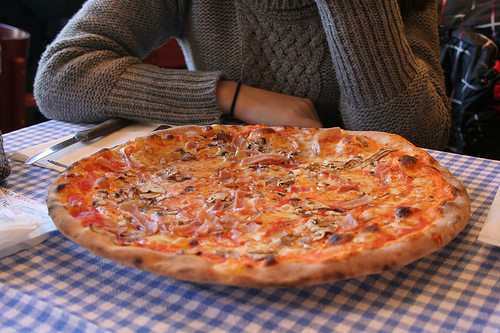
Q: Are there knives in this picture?
A: Yes, there is a knife.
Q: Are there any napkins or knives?
A: Yes, there is a knife.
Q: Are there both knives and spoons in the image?
A: No, there is a knife but no spoons.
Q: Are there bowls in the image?
A: No, there are no bowls.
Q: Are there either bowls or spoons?
A: No, there are no bowls or spoons.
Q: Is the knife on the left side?
A: Yes, the knife is on the left of the image.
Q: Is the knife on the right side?
A: No, the knife is on the left of the image.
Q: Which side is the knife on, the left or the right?
A: The knife is on the left of the image.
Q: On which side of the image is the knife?
A: The knife is on the left of the image.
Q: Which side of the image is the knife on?
A: The knife is on the left of the image.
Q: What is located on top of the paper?
A: The knife is on top of the paper.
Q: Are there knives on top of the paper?
A: Yes, there is a knife on top of the paper.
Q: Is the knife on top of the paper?
A: Yes, the knife is on top of the paper.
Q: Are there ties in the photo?
A: Yes, there is a tie.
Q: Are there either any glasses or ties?
A: Yes, there is a tie.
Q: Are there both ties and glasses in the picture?
A: No, there is a tie but no glasses.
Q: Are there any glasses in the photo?
A: No, there are no glasses.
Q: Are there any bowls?
A: No, there are no bowls.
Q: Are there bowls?
A: No, there are no bowls.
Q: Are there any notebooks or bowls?
A: No, there are no bowls or notebooks.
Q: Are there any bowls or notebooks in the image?
A: No, there are no bowls or notebooks.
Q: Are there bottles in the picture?
A: No, there are no bottles.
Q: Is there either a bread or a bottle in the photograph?
A: No, there are no bottles or breads.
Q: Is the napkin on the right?
A: Yes, the napkin is on the right of the image.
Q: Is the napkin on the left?
A: No, the napkin is on the right of the image.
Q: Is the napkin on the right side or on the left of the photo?
A: The napkin is on the right of the image.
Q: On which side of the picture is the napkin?
A: The napkin is on the right of the image.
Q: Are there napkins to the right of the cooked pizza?
A: Yes, there is a napkin to the right of the pizza.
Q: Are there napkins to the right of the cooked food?
A: Yes, there is a napkin to the right of the pizza.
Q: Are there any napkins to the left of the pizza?
A: No, the napkin is to the right of the pizza.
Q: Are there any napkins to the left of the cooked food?
A: No, the napkin is to the right of the pizza.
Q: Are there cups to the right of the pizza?
A: No, there is a napkin to the right of the pizza.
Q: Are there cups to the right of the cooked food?
A: No, there is a napkin to the right of the pizza.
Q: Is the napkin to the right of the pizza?
A: Yes, the napkin is to the right of the pizza.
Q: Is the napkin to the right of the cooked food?
A: Yes, the napkin is to the right of the pizza.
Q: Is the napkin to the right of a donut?
A: No, the napkin is to the right of the pizza.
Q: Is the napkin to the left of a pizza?
A: No, the napkin is to the right of a pizza.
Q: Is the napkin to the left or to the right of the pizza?
A: The napkin is to the right of the pizza.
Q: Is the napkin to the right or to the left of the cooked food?
A: The napkin is to the right of the pizza.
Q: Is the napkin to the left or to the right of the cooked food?
A: The napkin is to the right of the pizza.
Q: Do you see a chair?
A: Yes, there is a chair.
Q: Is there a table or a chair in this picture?
A: Yes, there is a chair.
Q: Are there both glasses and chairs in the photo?
A: No, there is a chair but no glasses.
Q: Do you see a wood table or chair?
A: Yes, there is a wood chair.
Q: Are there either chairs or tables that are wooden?
A: Yes, the chair is wooden.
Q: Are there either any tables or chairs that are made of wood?
A: Yes, the chair is made of wood.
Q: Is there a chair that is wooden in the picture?
A: Yes, there is a wood chair.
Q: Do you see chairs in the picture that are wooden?
A: Yes, there is a chair that is wooden.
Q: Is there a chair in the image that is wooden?
A: Yes, there is a chair that is wooden.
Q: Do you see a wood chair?
A: Yes, there is a chair that is made of wood.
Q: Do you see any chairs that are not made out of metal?
A: Yes, there is a chair that is made of wood.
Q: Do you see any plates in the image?
A: No, there are no plates.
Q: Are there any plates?
A: No, there are no plates.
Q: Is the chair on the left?
A: Yes, the chair is on the left of the image.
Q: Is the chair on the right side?
A: No, the chair is on the left of the image.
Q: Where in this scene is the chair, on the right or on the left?
A: The chair is on the left of the image.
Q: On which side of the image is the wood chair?
A: The chair is on the left of the image.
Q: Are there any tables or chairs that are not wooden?
A: No, there is a chair but it is wooden.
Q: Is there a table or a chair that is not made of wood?
A: No, there is a chair but it is made of wood.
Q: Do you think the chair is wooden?
A: Yes, the chair is wooden.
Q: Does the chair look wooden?
A: Yes, the chair is wooden.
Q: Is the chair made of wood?
A: Yes, the chair is made of wood.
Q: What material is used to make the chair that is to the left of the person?
A: The chair is made of wood.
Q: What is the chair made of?
A: The chair is made of wood.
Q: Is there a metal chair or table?
A: No, there is a chair but it is wooden.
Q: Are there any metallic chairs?
A: No, there is a chair but it is wooden.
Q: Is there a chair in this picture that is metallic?
A: No, there is a chair but it is wooden.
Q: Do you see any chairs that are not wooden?
A: No, there is a chair but it is wooden.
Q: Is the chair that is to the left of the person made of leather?
A: No, the chair is made of wood.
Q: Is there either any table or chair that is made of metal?
A: No, there is a chair but it is made of wood.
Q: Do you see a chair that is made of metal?
A: No, there is a chair but it is made of wood.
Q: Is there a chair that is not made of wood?
A: No, there is a chair but it is made of wood.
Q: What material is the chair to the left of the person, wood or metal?
A: The chair is made of wood.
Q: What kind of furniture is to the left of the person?
A: The piece of furniture is a chair.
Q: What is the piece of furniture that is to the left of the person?
A: The piece of furniture is a chair.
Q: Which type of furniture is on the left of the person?
A: The piece of furniture is a chair.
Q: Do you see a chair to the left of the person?
A: Yes, there is a chair to the left of the person.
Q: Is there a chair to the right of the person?
A: No, the chair is to the left of the person.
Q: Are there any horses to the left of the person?
A: No, there is a chair to the left of the person.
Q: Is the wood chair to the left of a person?
A: Yes, the chair is to the left of a person.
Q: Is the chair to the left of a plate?
A: No, the chair is to the left of a person.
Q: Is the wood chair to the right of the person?
A: No, the chair is to the left of the person.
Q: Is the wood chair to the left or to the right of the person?
A: The chair is to the left of the person.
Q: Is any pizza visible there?
A: Yes, there is a pizza.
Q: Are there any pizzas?
A: Yes, there is a pizza.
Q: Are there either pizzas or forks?
A: Yes, there is a pizza.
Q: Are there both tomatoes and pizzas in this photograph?
A: No, there is a pizza but no tomatoes.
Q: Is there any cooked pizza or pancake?
A: Yes, there is a cooked pizza.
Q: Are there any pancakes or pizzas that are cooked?
A: Yes, the pizza is cooked.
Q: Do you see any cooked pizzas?
A: Yes, there is a cooked pizza.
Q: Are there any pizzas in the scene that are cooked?
A: Yes, there is a pizza that is cooked.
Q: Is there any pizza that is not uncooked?
A: Yes, there is an cooked pizza.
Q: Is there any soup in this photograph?
A: No, there is no soup.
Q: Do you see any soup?
A: No, there is no soup.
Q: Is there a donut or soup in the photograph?
A: No, there are no soup or donuts.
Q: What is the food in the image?
A: The food is a pizza.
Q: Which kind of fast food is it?
A: The food is a pizza.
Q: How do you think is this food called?
A: This is a pizza.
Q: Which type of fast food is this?
A: This is a pizza.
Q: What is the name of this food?
A: This is a pizza.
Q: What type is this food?
A: This is a pizza.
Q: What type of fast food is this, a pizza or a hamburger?
A: This is a pizza.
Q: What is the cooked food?
A: The food is a pizza.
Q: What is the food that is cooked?
A: The food is a pizza.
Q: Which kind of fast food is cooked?
A: The fast food is a pizza.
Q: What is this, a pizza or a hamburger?
A: This is a pizza.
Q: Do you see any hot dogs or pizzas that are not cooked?
A: No, there is a pizza but it is cooked.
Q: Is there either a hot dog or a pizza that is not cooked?
A: No, there is a pizza but it is cooked.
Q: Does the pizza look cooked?
A: Yes, the pizza is cooked.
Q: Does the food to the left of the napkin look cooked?
A: Yes, the pizza is cooked.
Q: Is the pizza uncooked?
A: No, the pizza is cooked.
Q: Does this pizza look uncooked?
A: No, the pizza is cooked.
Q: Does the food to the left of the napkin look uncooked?
A: No, the pizza is cooked.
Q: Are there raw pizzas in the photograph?
A: No, there is a pizza but it is cooked.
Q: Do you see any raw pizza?
A: No, there is a pizza but it is cooked.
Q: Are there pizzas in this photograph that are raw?
A: No, there is a pizza but it is cooked.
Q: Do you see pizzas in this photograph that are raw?
A: No, there is a pizza but it is cooked.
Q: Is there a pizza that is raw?
A: No, there is a pizza but it is cooked.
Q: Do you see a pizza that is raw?
A: No, there is a pizza but it is cooked.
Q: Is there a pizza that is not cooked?
A: No, there is a pizza but it is cooked.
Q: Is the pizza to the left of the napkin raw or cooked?
A: The pizza is cooked.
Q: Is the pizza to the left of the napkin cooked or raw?
A: The pizza is cooked.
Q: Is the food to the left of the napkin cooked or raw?
A: The pizza is cooked.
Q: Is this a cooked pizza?
A: Yes, this is a cooked pizza.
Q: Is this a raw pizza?
A: No, this is a cooked pizza.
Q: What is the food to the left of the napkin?
A: The food is a pizza.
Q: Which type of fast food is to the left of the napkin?
A: The food is a pizza.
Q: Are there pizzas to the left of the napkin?
A: Yes, there is a pizza to the left of the napkin.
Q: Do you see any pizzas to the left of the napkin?
A: Yes, there is a pizza to the left of the napkin.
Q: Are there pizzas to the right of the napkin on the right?
A: No, the pizza is to the left of the napkin.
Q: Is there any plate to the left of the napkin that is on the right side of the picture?
A: No, there is a pizza to the left of the napkin.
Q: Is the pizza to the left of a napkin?
A: Yes, the pizza is to the left of a napkin.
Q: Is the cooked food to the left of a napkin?
A: Yes, the pizza is to the left of a napkin.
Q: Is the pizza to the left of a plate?
A: No, the pizza is to the left of a napkin.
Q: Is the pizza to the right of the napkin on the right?
A: No, the pizza is to the left of the napkin.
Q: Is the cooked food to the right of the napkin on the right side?
A: No, the pizza is to the left of the napkin.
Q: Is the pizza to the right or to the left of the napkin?
A: The pizza is to the left of the napkin.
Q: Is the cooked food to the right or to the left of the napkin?
A: The pizza is to the left of the napkin.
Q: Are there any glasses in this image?
A: No, there are no glasses.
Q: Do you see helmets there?
A: No, there are no helmets.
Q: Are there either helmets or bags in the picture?
A: No, there are no helmets or bags.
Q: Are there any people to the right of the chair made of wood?
A: Yes, there is a person to the right of the chair.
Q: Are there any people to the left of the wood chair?
A: No, the person is to the right of the chair.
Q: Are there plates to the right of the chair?
A: No, there is a person to the right of the chair.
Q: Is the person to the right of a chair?
A: Yes, the person is to the right of a chair.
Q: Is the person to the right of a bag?
A: No, the person is to the right of a chair.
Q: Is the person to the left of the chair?
A: No, the person is to the right of the chair.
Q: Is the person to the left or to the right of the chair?
A: The person is to the right of the chair.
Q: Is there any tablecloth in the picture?
A: Yes, there is a tablecloth.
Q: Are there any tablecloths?
A: Yes, there is a tablecloth.